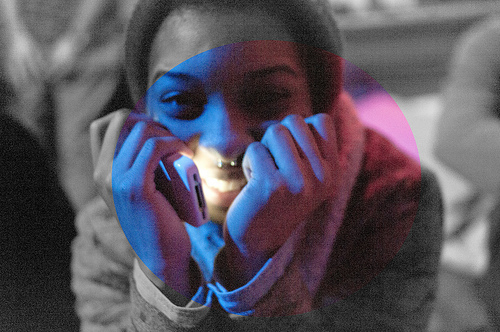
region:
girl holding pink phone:
[56, 109, 224, 271]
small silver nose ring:
[205, 157, 235, 187]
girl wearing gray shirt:
[82, 146, 437, 318]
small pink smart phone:
[153, 137, 218, 241]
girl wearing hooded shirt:
[46, 78, 476, 329]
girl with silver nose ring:
[91, 33, 299, 203]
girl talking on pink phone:
[56, 84, 336, 246]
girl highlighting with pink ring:
[148, 32, 495, 323]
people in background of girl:
[0, 4, 200, 175]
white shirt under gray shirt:
[114, 231, 413, 316]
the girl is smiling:
[178, 163, 253, 203]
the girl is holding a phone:
[78, 101, 215, 301]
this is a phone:
[114, 134, 211, 236]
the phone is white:
[133, 139, 216, 235]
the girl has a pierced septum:
[213, 150, 241, 174]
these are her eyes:
[155, 74, 300, 121]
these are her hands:
[79, 98, 350, 281]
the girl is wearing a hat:
[115, 1, 356, 126]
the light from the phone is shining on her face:
[123, 115, 246, 234]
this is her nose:
[201, 103, 261, 173]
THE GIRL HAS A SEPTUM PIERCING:
[209, 155, 240, 172]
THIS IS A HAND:
[216, 108, 358, 265]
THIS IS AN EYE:
[243, 80, 307, 116]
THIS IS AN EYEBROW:
[142, 58, 204, 99]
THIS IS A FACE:
[136, 7, 333, 232]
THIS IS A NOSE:
[197, 96, 256, 175]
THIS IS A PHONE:
[138, 139, 213, 241]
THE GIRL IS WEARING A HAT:
[118, 0, 362, 130]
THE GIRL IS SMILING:
[180, 149, 255, 211]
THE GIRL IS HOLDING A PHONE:
[142, 152, 214, 227]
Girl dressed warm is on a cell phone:
[63, 2, 450, 312]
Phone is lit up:
[136, 139, 233, 244]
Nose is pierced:
[198, 144, 245, 185]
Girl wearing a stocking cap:
[103, 18, 356, 119]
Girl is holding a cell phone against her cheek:
[75, 51, 240, 256]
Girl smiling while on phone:
[185, 159, 260, 210]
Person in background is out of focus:
[6, 0, 116, 120]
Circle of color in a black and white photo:
[117, 37, 429, 291]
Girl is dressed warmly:
[30, 116, 455, 328]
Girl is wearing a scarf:
[286, 94, 412, 289]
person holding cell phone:
[87, 2, 442, 330]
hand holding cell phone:
[80, 105, 205, 291]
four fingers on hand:
[85, 108, 176, 191]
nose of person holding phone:
[201, 126, 250, 173]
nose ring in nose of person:
[215, 152, 238, 171]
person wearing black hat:
[104, 0, 341, 116]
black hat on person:
[113, 0, 352, 108]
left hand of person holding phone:
[228, 112, 353, 262]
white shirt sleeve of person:
[210, 239, 310, 302]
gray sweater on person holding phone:
[58, 120, 475, 330]